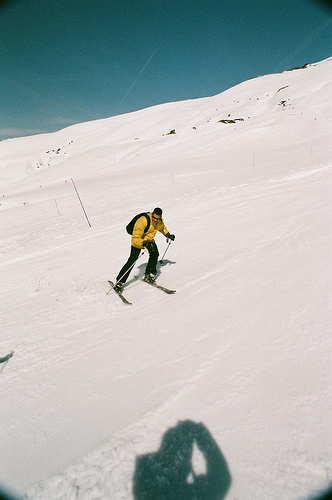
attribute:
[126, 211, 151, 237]
backpack — black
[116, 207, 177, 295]
skier — male, skiing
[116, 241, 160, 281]
pants — black, ski pants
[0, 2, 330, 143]
sky — blue, cloudless, dark blue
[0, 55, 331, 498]
slope — snow covered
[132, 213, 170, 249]
ski jacket — yellow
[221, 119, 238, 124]
rock — snow covered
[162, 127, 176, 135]
rock — snow covered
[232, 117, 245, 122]
rock — snow covered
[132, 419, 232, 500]
shadow — of a person, person with camera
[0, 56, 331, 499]
snow — white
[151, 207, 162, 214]
hair — dark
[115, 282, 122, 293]
boot — dark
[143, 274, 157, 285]
boot — dark